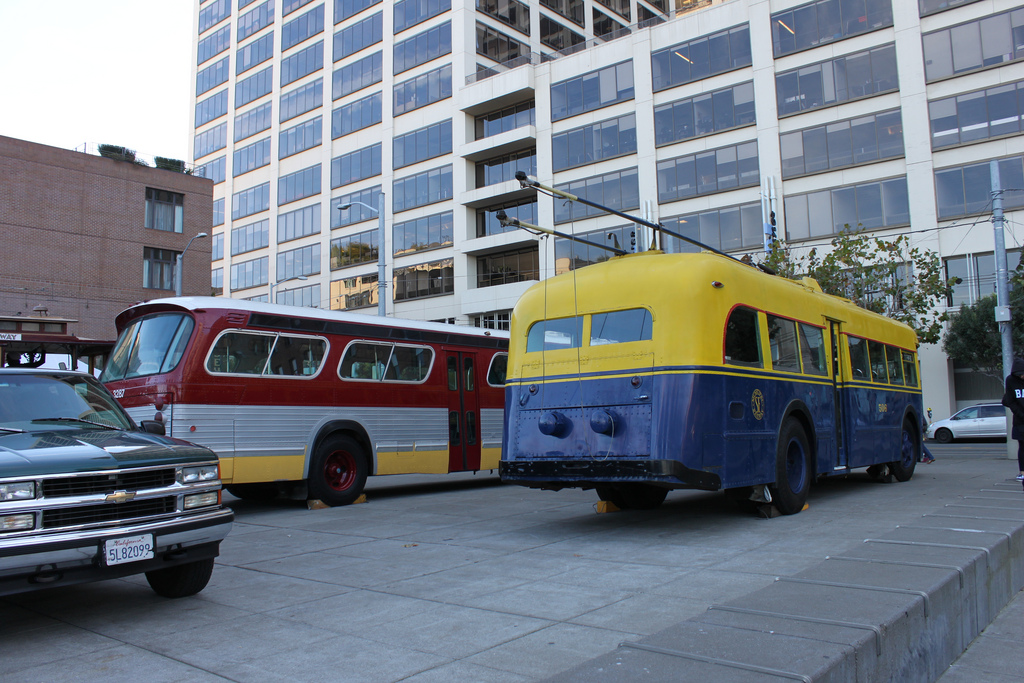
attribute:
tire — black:
[767, 417, 824, 513]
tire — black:
[885, 412, 925, 489]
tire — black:
[585, 471, 675, 528]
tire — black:
[303, 414, 377, 513]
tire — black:
[141, 532, 218, 608]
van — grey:
[916, 396, 1014, 448]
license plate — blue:
[92, 520, 169, 578]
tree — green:
[546, 244, 968, 359]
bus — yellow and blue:
[446, 244, 968, 530]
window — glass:
[224, 57, 282, 114]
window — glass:
[271, 68, 323, 139]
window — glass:
[379, 155, 452, 220]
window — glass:
[537, 54, 642, 132]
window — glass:
[644, 124, 774, 214]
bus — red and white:
[88, 264, 496, 512]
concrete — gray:
[3, 440, 1022, 672]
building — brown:
[8, 127, 234, 418]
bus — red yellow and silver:
[88, 295, 516, 508]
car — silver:
[925, 374, 1014, 457]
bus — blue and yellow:
[491, 251, 919, 512]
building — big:
[172, 11, 991, 444]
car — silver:
[929, 394, 1010, 442]